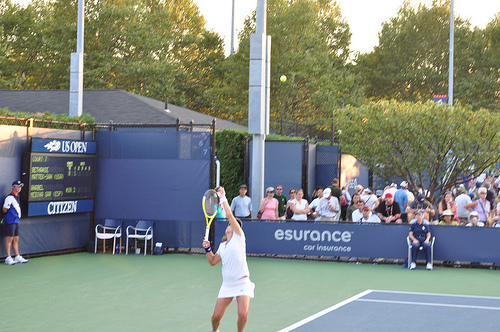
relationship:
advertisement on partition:
[265, 225, 361, 259] [214, 219, 496, 269]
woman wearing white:
[198, 185, 258, 332] [218, 235, 249, 294]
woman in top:
[259, 183, 284, 223] [261, 197, 281, 217]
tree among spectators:
[332, 100, 496, 212] [239, 186, 496, 223]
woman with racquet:
[198, 185, 258, 332] [201, 187, 225, 251]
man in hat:
[380, 194, 404, 220] [384, 190, 393, 197]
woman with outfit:
[198, 185, 258, 332] [213, 231, 253, 301]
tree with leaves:
[332, 100, 496, 212] [381, 121, 402, 133]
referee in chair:
[409, 208, 436, 268] [404, 232, 436, 270]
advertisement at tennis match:
[265, 225, 361, 259] [4, 244, 496, 331]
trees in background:
[113, 14, 420, 133] [3, 4, 499, 122]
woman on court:
[198, 185, 258, 332] [135, 258, 494, 329]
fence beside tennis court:
[8, 122, 209, 250] [135, 258, 494, 329]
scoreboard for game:
[24, 136, 108, 219] [377, 293, 469, 330]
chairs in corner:
[95, 222, 154, 254] [86, 237, 93, 249]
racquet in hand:
[201, 187, 225, 251] [201, 237, 214, 253]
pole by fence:
[209, 115, 221, 186] [8, 122, 209, 250]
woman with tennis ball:
[198, 185, 258, 332] [271, 71, 293, 86]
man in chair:
[409, 208, 436, 268] [404, 232, 436, 270]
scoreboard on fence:
[24, 136, 108, 219] [8, 122, 209, 250]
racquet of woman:
[201, 187, 225, 251] [194, 185, 265, 332]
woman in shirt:
[259, 183, 284, 223] [261, 197, 281, 217]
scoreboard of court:
[24, 136, 108, 219] [135, 258, 494, 329]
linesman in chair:
[409, 208, 436, 268] [404, 232, 436, 270]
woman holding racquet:
[198, 185, 258, 332] [201, 187, 225, 251]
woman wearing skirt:
[198, 185, 258, 332] [217, 279, 259, 301]